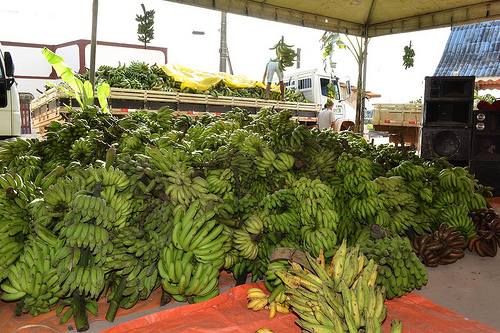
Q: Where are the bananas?
A: On the tarps.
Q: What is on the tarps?
A: Bananas.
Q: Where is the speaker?
A: Behind the bananas.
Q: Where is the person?
A: On the truck.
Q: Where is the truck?
A: Next to the bananas.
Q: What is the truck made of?
A: Metal.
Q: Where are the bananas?
A: On the tarps.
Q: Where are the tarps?
A: On the floor.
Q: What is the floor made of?
A: Cement.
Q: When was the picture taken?
A: Day time.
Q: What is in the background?
A: Sky.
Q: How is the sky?
A: Gray.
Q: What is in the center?
A: Bananas.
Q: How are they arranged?
A: Piled against each other.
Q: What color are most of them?
A: Green.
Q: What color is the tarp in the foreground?
A: A shade of orange.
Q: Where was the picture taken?
A: At a market.